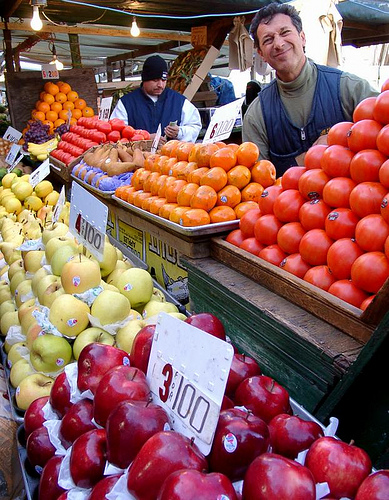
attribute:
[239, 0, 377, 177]
man — happy, working, smiling, middle-aged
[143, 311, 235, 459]
sign — white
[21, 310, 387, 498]
apples — shiny, red, stacked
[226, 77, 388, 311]
tomatoes — displayed, stacked, orange-red, piled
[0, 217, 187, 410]
apples — yellow, stacked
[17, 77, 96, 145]
oranges — stacked, priced, piled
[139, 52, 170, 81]
hat — black, knit, knitted, blue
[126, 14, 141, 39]
light bulb — hanging, bare, glowing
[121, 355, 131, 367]
sticker — oval, white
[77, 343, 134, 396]
apple — red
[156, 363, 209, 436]
writing — red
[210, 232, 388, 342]
case — brown, wooden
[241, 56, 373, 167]
shirt — grey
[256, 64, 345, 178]
vest — blue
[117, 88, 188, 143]
vest — blue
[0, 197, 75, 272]
pears — piled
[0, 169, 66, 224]
lemons — piled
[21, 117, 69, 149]
grapes — purple, stacked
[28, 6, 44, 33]
light bulb — hanging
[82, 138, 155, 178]
sweet potatoes — stacked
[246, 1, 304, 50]
hair — dark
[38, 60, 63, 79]
sign — small, white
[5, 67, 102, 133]
board — wooden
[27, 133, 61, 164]
bananas — yellow